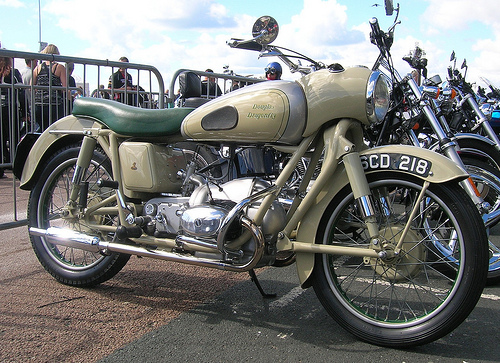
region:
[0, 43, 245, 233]
a steel gate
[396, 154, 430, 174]
218 on wheel cover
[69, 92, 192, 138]
a green seat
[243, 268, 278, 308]
a kick stand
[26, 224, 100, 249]
a chrome pipe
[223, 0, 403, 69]
the handle bars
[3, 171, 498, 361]
the grey pavement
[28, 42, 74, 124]
a lady standing in tank top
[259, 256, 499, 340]
white line on street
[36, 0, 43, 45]
a steel pole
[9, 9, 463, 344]
this is a motorcycle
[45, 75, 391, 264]
the motorcycle is vintage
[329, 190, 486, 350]
the wheel is made of rubber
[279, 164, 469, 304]
the rubber is black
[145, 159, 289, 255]
this is the engine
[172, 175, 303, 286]
the engine is silver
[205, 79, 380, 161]
the body of the motorcycle is gold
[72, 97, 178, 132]
the seat is turqoise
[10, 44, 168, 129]
these are spectators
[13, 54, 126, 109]
this is a metal fence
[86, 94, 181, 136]
Green seat on bike.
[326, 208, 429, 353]
Front tire on bike is black.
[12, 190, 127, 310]
Back tire on bike is black.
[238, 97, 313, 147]
Green writing on side of bike.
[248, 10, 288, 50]
Silver mirror on handlebars.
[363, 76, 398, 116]
Large light on front of bike.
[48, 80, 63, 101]
Person wearing tank top.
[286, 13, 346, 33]
White clouds in sky.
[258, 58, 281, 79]
Person wearing helmet on head.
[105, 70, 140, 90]
Person wearing black shirt.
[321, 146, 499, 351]
The front wheel of an old motorcycle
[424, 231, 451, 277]
spokes of a motorcycle wheel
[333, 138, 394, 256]
The front shock of a motorcycle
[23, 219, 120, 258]
The chrome exhaust pipe of a motorcycle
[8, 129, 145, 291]
the rear wheel of a motorcycle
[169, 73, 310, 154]
the gas tank of a motorcycle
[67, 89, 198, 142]
a green seat of a motorcycle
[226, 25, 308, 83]
the right handlebar of a motorcycle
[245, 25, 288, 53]
the right mirror of a motorcycle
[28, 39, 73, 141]
a person standing behind a metal fence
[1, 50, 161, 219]
the barrier is metal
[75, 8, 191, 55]
white clouds in the sky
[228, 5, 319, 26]
patch of blue sky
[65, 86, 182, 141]
the green seat of the motorcycle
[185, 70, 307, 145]
the tank of the motorcycle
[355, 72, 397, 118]
headlight of the motorcycle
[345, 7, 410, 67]
handlebar of the motorcycle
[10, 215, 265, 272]
muffler of the motorcycle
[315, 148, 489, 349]
front tire of the motorcycle